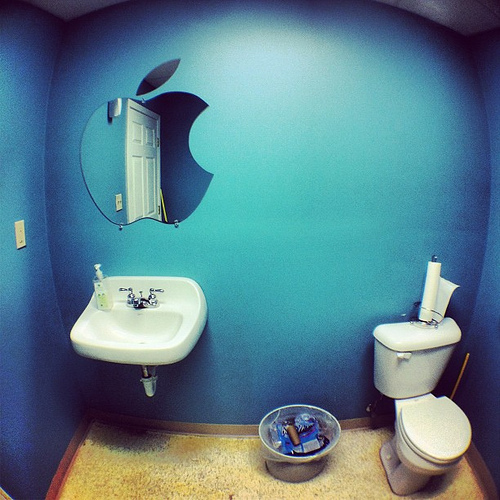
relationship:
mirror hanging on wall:
[78, 57, 214, 226] [43, 1, 491, 435]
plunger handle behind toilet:
[449, 351, 472, 402] [371, 316, 474, 497]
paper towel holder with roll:
[407, 255, 445, 330] [419, 262, 461, 322]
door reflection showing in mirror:
[125, 98, 164, 225] [78, 57, 214, 226]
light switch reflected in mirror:
[115, 193, 124, 211] [78, 57, 214, 226]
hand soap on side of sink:
[91, 262, 114, 313] [69, 275, 209, 366]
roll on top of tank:
[419, 262, 461, 322] [371, 317, 463, 400]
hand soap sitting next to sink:
[91, 262, 114, 313] [69, 275, 209, 366]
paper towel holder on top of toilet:
[407, 255, 445, 330] [371, 316, 474, 497]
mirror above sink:
[78, 57, 214, 226] [69, 275, 209, 366]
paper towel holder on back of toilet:
[407, 255, 445, 330] [371, 316, 474, 497]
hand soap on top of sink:
[91, 262, 114, 313] [69, 275, 209, 366]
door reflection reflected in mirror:
[125, 98, 164, 225] [78, 57, 214, 226]